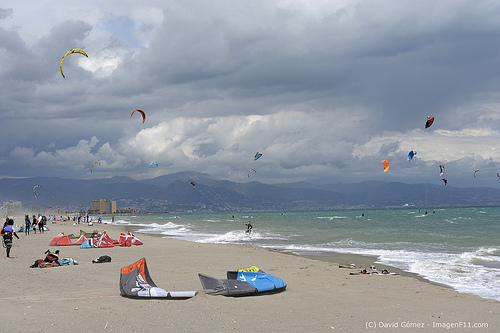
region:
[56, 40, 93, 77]
Yellow kitesurfing kite being used by a surfer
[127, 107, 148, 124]
Red kitesurfing kite being used by a surfer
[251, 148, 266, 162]
Multicolored kitesurfing kite being used by a surfer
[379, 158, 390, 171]
Orange kitesurfing kite being used by a surfer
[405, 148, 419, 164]
Blue and white kitesurfing kite being used by a surfer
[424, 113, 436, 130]
Multi colored kitesurfing kite being used by a surfer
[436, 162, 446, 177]
White and blue kitesurfing kite being used by a surfer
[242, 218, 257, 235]
Man kitesurfing near the shore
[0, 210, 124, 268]
People on the beach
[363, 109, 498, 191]
Group of kitesurfing kites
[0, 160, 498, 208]
mountain line in the background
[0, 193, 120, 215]
tall buildings in the background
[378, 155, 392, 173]
an orange kite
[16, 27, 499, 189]
kites flying in the air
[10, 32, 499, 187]
kites in the cloudy sky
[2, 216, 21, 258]
a person holding a kite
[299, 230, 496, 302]
sand and water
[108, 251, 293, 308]
kites on the ground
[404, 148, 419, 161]
a blue kite in the air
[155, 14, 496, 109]
dark clouds in the sky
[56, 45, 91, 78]
yellow sail over a beach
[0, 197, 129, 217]
buildings near a beach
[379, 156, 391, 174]
orange sail over the ocean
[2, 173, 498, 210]
mountains near an ocean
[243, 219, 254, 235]
person near shore holding onto ropes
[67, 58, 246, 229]
white ropes connected to sails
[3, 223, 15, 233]
person on the beach in a blue top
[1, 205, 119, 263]
people on a sandy beach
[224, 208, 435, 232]
people in the ocean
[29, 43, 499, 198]
many sails in the sky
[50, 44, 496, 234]
kites at the beach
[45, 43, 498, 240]
kites flying over the ocean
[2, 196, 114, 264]
people at the ocean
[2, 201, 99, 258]
people standing in the sand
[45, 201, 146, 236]
people near the water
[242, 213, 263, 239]
a person in the water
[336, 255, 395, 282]
shoes in the sand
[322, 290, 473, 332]
sand at the ocean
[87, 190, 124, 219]
buildings on the far shore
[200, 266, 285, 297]
a blue kite on the beach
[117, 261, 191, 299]
an orange kite on the beach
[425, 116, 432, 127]
a red kite in the air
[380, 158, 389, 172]
an orange kite in the air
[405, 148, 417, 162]
a bluekite in the air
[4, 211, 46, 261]
people standing on a beach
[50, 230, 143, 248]
red fabric on the beach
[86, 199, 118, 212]
buildings in the distance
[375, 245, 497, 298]
white foam on a beach